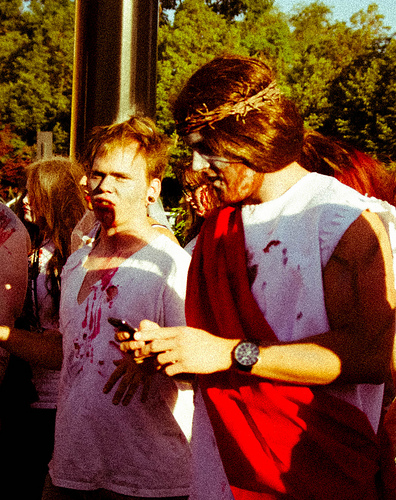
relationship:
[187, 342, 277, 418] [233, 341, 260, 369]
watch keep clock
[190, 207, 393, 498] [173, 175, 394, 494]
sash around body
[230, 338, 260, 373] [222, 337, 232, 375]
watch around wrist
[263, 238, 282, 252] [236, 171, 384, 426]
red spot on fabric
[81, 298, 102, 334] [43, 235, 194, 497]
stains on shirt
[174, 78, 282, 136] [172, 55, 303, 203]
headband around head